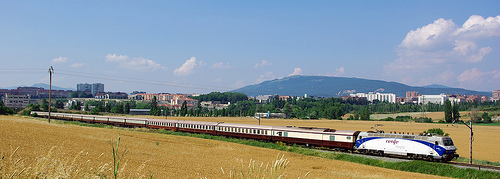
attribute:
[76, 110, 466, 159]
train — long, blue, moving, travelling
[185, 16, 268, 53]
mountain — beautiful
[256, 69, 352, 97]
mountain — blue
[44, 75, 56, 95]
pole — brown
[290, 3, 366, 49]
sky — blue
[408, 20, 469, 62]
clouds — white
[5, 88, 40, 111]
buildings — factories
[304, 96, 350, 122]
trees — green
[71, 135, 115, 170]
field — brown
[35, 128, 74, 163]
grass — brown, yellow, green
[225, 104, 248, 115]
shrubs — green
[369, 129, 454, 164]
car — white, beige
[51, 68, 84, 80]
wires — electrice lines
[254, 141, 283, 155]
plants — wire